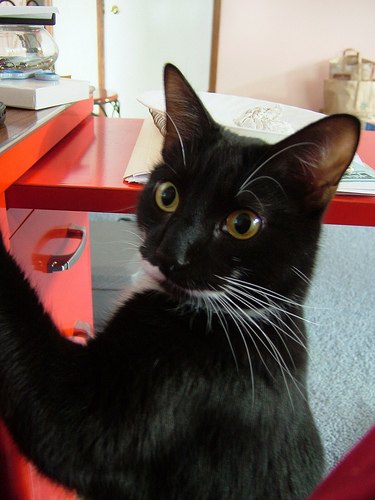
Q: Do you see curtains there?
A: No, there are no curtains.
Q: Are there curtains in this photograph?
A: No, there are no curtains.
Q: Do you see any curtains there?
A: No, there are no curtains.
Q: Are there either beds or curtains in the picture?
A: No, there are no curtains or beds.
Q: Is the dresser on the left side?
A: Yes, the dresser is on the left of the image.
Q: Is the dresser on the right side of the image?
A: No, the dresser is on the left of the image.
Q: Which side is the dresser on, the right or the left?
A: The dresser is on the left of the image.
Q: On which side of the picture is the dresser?
A: The dresser is on the left of the image.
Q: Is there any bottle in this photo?
A: Yes, there is a bottle.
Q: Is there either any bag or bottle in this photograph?
A: Yes, there is a bottle.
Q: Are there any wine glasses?
A: No, there are no wine glasses.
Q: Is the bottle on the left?
A: Yes, the bottle is on the left of the image.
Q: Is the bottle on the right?
A: No, the bottle is on the left of the image.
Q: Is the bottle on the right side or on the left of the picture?
A: The bottle is on the left of the image.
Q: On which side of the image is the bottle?
A: The bottle is on the left of the image.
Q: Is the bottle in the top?
A: Yes, the bottle is in the top of the image.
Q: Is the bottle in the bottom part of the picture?
A: No, the bottle is in the top of the image.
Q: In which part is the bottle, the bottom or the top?
A: The bottle is in the top of the image.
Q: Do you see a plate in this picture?
A: Yes, there is a plate.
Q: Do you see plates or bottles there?
A: Yes, there is a plate.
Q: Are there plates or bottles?
A: Yes, there is a plate.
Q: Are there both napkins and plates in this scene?
A: No, there is a plate but no napkins.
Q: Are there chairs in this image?
A: No, there are no chairs.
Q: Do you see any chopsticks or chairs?
A: No, there are no chairs or chopsticks.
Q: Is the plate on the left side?
A: Yes, the plate is on the left of the image.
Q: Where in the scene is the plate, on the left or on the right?
A: The plate is on the left of the image.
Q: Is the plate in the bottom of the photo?
A: No, the plate is in the top of the image.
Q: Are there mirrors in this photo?
A: No, there are no mirrors.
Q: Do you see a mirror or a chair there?
A: No, there are no mirrors or chairs.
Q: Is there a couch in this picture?
A: No, there are no couches.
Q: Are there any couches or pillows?
A: No, there are no couches or pillows.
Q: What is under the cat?
A: The carpet is under the cat.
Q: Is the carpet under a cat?
A: Yes, the carpet is under a cat.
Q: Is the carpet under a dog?
A: No, the carpet is under a cat.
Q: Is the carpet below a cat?
A: Yes, the carpet is below a cat.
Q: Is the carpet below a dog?
A: No, the carpet is below a cat.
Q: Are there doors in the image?
A: Yes, there is a door.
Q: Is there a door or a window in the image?
A: Yes, there is a door.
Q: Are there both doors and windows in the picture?
A: No, there is a door but no windows.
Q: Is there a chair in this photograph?
A: No, there are no chairs.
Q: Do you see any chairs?
A: No, there are no chairs.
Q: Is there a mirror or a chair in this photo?
A: No, there are no chairs or mirrors.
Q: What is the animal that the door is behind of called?
A: The animal is a cat.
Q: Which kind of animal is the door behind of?
A: The door is behind the cat.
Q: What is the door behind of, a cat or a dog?
A: The door is behind a cat.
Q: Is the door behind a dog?
A: No, the door is behind the cat.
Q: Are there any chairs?
A: No, there are no chairs.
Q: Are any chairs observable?
A: No, there are no chairs.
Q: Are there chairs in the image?
A: No, there are no chairs.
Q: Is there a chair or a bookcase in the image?
A: No, there are no chairs or bookcases.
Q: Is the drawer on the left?
A: Yes, the drawer is on the left of the image.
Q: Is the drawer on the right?
A: No, the drawer is on the left of the image.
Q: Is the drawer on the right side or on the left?
A: The drawer is on the left of the image.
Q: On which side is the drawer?
A: The drawer is on the left of the image.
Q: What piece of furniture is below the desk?
A: The piece of furniture is a drawer.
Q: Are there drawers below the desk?
A: Yes, there is a drawer below the desk.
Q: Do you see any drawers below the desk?
A: Yes, there is a drawer below the desk.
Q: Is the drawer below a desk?
A: Yes, the drawer is below a desk.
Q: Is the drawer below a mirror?
A: No, the drawer is below a desk.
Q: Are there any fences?
A: No, there are no fences.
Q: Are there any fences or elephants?
A: No, there are no fences or elephants.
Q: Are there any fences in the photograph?
A: No, there are no fences.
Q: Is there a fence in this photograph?
A: No, there are no fences.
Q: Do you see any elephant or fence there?
A: No, there are no fences or elephants.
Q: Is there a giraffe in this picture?
A: No, there are no giraffes.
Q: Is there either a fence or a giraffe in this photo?
A: No, there are no giraffes or fences.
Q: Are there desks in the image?
A: Yes, there is a desk.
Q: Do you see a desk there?
A: Yes, there is a desk.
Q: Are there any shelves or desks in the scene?
A: Yes, there is a desk.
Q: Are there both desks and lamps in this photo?
A: No, there is a desk but no lamps.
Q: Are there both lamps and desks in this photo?
A: No, there is a desk but no lamps.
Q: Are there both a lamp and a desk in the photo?
A: No, there is a desk but no lamps.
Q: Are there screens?
A: No, there are no screens.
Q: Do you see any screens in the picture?
A: No, there are no screens.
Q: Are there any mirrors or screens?
A: No, there are no screens or mirrors.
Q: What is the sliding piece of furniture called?
A: The piece of furniture is a desk.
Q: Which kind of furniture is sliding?
A: The furniture is a desk.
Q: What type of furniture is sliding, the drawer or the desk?
A: The desk is sliding.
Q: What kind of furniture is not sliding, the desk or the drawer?
A: The drawer is not sliding.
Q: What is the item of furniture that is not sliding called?
A: The piece of furniture is a drawer.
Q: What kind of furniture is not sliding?
A: The furniture is a drawer.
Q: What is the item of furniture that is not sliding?
A: The piece of furniture is a drawer.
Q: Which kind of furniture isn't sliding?
A: The furniture is a drawer.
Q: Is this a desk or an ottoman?
A: This is a desk.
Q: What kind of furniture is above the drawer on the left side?
A: The piece of furniture is a desk.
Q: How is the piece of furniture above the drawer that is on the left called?
A: The piece of furniture is a desk.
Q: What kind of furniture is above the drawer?
A: The piece of furniture is a desk.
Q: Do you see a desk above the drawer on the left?
A: Yes, there is a desk above the drawer.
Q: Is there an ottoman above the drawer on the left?
A: No, there is a desk above the drawer.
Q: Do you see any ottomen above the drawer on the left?
A: No, there is a desk above the drawer.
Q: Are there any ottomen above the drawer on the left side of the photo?
A: No, there is a desk above the drawer.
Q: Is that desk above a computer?
A: No, the desk is above the drawer.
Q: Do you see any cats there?
A: Yes, there is a cat.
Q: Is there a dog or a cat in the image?
A: Yes, there is a cat.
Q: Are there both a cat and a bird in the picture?
A: No, there is a cat but no birds.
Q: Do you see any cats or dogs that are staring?
A: Yes, the cat is staring.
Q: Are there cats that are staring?
A: Yes, there is a cat that is staring.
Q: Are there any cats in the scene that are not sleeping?
A: Yes, there is a cat that is staring.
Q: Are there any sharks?
A: No, there are no sharks.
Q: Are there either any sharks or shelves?
A: No, there are no sharks or shelves.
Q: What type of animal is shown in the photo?
A: The animal is a cat.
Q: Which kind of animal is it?
A: The animal is a cat.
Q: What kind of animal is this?
A: This is a cat.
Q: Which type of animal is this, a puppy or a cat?
A: This is a cat.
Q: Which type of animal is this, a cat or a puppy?
A: This is a cat.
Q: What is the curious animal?
A: The animal is a cat.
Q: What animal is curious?
A: The animal is a cat.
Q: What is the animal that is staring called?
A: The animal is a cat.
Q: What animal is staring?
A: The animal is a cat.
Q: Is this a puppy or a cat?
A: This is a cat.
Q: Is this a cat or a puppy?
A: This is a cat.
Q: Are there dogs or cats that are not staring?
A: No, there is a cat but it is staring.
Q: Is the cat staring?
A: Yes, the cat is staring.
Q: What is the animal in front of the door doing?
A: The cat is staring.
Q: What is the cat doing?
A: The cat is staring.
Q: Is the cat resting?
A: No, the cat is staring.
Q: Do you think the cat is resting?
A: No, the cat is staring.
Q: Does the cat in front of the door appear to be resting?
A: No, the cat is staring.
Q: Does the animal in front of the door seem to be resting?
A: No, the cat is staring.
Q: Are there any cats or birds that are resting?
A: No, there is a cat but it is staring.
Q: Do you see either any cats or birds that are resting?
A: No, there is a cat but it is staring.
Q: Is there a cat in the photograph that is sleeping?
A: No, there is a cat but it is staring.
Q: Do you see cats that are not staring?
A: No, there is a cat but it is staring.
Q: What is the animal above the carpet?
A: The animal is a cat.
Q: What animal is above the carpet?
A: The animal is a cat.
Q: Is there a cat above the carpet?
A: Yes, there is a cat above the carpet.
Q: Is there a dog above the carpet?
A: No, there is a cat above the carpet.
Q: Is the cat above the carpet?
A: Yes, the cat is above the carpet.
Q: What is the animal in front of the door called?
A: The animal is a cat.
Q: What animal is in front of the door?
A: The animal is a cat.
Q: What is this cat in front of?
A: The cat is in front of the door.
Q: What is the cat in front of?
A: The cat is in front of the door.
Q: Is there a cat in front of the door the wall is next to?
A: Yes, there is a cat in front of the door.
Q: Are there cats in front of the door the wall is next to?
A: Yes, there is a cat in front of the door.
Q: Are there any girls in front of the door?
A: No, there is a cat in front of the door.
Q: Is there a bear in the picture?
A: No, there are no bears.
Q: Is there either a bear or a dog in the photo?
A: No, there are no bears or dogs.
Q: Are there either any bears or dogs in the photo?
A: No, there are no bears or dogs.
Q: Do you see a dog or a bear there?
A: No, there are no bears or dogs.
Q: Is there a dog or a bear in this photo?
A: No, there are no bears or dogs.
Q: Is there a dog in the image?
A: No, there are no dogs.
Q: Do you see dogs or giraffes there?
A: No, there are no dogs or giraffes.